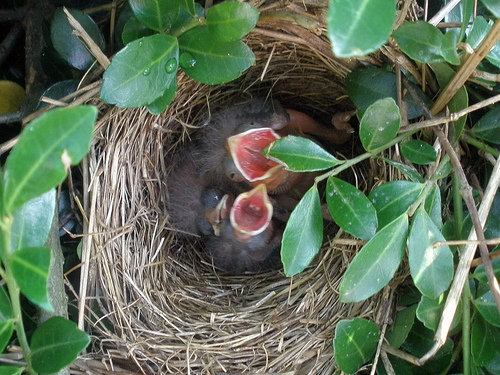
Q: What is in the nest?
A: Birds.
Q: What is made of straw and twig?
A: Nest.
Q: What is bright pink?
A: The bird's mouths.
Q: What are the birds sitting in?
A: Nest.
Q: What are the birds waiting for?
A: Food.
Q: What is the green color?
A: Leaves.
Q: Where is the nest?
A: In a tree.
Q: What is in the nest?
A: Baby birds.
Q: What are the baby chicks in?
A: A nest.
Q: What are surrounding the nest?
A: Leaves.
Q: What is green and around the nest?
A: Leaves.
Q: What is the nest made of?
A: Straw.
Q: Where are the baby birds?
A: In the center of the nest.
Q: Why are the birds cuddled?
A: To keep warm.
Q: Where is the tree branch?
A: Over the nest.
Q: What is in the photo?
A: Some birds.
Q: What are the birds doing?
A: Opening mouths.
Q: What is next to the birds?
A: Leaves.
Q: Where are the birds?
A: In the nest.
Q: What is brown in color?
A: The nest.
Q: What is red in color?
A: The inside of the bird's mouth.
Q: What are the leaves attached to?
A: Branches.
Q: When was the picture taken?
A: Daytime.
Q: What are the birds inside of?
A: A nest.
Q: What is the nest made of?
A: Grass.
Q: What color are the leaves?
A: Green.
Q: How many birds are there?
A: Three.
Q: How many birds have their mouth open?
A: Two.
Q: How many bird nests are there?
A: One.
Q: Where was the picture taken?
A: A bird nest.